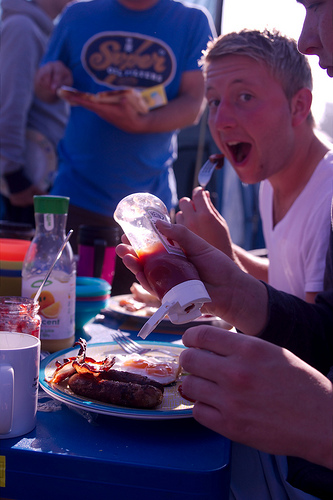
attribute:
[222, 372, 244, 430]
spots — red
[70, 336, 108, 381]
bacon — crunchy, curled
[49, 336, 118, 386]
bacon — crispy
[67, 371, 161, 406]
brown sausage — large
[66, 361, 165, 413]
sausage — brown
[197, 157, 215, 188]
fork — stainless steel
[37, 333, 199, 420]
plate — white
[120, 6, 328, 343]
shirt — white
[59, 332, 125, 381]
bacon — crispy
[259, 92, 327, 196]
guy's — blonde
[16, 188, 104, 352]
bottle — clear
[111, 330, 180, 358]
fork — silver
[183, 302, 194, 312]
ketchup — red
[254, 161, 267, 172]
spot — red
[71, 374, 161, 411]
sausage — cooked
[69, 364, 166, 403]
sausage — cooked